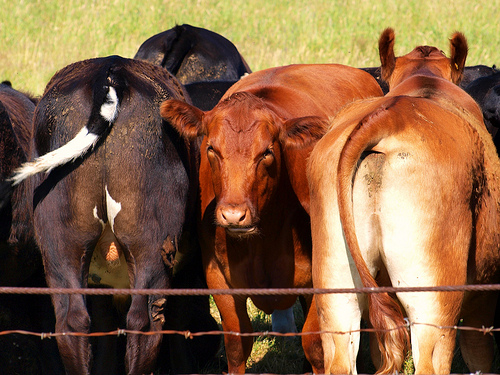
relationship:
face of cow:
[153, 90, 339, 241] [157, 62, 385, 372]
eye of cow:
[252, 146, 275, 164] [172, 70, 324, 272]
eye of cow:
[204, 137, 224, 160] [172, 70, 324, 272]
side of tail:
[352, 194, 369, 275] [336, 110, 409, 363]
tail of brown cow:
[333, 103, 419, 374] [159, 64, 387, 375]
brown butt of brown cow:
[309, 96, 466, 285] [159, 64, 387, 375]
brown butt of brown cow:
[309, 96, 466, 285] [296, 24, 498, 371]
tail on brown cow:
[333, 103, 419, 374] [296, 24, 498, 371]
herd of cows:
[0, 27, 492, 357] [188, 62, 370, 373]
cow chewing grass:
[157, 62, 385, 372] [3, 2, 485, 103]